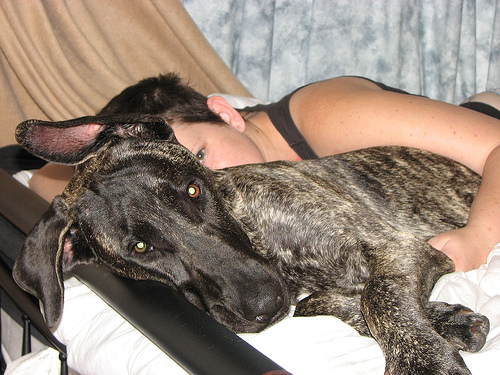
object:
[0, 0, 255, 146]
drape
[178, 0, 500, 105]
drapes